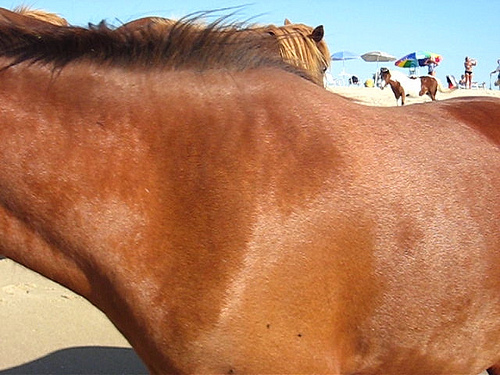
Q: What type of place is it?
A: It is a beach.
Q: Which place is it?
A: It is a beach.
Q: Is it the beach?
A: Yes, it is the beach.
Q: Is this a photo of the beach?
A: Yes, it is showing the beach.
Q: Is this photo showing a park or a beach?
A: It is showing a beach.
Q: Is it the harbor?
A: No, it is the beach.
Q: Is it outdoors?
A: Yes, it is outdoors.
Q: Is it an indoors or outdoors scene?
A: It is outdoors.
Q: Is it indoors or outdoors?
A: It is outdoors.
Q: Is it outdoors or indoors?
A: It is outdoors.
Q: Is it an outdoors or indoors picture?
A: It is outdoors.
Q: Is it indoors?
A: No, it is outdoors.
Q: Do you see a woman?
A: Yes, there is a woman.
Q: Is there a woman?
A: Yes, there is a woman.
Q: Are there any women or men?
A: Yes, there is a woman.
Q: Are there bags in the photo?
A: No, there are no bags.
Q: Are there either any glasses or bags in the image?
A: No, there are no bags or glasses.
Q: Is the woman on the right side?
A: Yes, the woman is on the right of the image.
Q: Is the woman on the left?
A: No, the woman is on the right of the image.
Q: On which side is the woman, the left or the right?
A: The woman is on the right of the image.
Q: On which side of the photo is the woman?
A: The woman is on the right of the image.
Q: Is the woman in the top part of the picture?
A: Yes, the woman is in the top of the image.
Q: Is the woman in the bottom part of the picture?
A: No, the woman is in the top of the image.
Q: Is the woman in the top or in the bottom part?
A: The woman is in the top of the image.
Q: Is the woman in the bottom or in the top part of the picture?
A: The woman is in the top of the image.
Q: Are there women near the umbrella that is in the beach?
A: Yes, there is a woman near the umbrella.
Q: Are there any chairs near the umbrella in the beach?
A: No, there is a woman near the umbrella.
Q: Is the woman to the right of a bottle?
A: No, the woman is to the right of the umbrella.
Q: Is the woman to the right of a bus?
A: No, the woman is to the right of the umbrella.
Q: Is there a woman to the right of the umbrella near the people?
A: Yes, there is a woman to the right of the umbrella.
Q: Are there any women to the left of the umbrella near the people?
A: No, the woman is to the right of the umbrella.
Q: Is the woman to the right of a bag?
A: No, the woman is to the right of the umbrella.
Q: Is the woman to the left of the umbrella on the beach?
A: No, the woman is to the right of the umbrella.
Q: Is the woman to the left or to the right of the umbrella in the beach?
A: The woman is to the right of the umbrella.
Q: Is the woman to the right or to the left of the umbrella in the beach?
A: The woman is to the right of the umbrella.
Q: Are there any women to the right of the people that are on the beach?
A: Yes, there is a woman to the right of the people.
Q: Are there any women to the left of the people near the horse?
A: No, the woman is to the right of the people.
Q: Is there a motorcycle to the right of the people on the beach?
A: No, there is a woman to the right of the people.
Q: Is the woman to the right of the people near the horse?
A: Yes, the woman is to the right of the people.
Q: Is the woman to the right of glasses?
A: No, the woman is to the right of the people.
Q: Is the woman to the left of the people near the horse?
A: No, the woman is to the right of the people.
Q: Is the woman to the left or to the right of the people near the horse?
A: The woman is to the right of the people.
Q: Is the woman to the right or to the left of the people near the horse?
A: The woman is to the right of the people.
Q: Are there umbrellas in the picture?
A: Yes, there is an umbrella.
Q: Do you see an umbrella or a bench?
A: Yes, there is an umbrella.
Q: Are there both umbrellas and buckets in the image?
A: No, there is an umbrella but no buckets.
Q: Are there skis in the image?
A: No, there are no skis.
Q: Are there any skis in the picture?
A: No, there are no skis.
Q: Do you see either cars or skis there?
A: No, there are no skis or cars.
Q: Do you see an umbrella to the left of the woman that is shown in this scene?
A: Yes, there is an umbrella to the left of the woman.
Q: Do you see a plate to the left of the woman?
A: No, there is an umbrella to the left of the woman.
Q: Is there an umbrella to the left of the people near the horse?
A: Yes, there is an umbrella to the left of the people.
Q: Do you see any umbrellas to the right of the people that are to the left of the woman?
A: No, the umbrella is to the left of the people.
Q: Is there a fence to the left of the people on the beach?
A: No, there is an umbrella to the left of the people.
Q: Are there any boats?
A: No, there are no boats.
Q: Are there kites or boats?
A: No, there are no boats or kites.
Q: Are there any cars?
A: No, there are no cars.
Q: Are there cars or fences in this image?
A: No, there are no cars or fences.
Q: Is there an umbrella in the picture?
A: Yes, there is an umbrella.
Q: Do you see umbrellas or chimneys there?
A: Yes, there is an umbrella.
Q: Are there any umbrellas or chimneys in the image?
A: Yes, there is an umbrella.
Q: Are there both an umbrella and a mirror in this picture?
A: No, there is an umbrella but no mirrors.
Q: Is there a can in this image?
A: No, there are no cans.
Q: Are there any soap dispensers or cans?
A: No, there are no cans or soap dispensers.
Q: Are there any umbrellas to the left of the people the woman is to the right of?
A: Yes, there is an umbrella to the left of the people.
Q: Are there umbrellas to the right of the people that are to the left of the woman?
A: No, the umbrella is to the left of the people.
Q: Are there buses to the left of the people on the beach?
A: No, there is an umbrella to the left of the people.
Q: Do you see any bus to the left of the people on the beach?
A: No, there is an umbrella to the left of the people.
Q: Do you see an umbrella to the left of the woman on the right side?
A: Yes, there is an umbrella to the left of the woman.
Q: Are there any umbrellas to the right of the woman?
A: No, the umbrella is to the left of the woman.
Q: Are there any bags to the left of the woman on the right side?
A: No, there is an umbrella to the left of the woman.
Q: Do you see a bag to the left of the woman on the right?
A: No, there is an umbrella to the left of the woman.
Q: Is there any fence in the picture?
A: No, there are no fences.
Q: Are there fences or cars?
A: No, there are no fences or cars.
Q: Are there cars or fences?
A: No, there are no fences or cars.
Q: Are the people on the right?
A: Yes, the people are on the right of the image.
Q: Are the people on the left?
A: No, the people are on the right of the image.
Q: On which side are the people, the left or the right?
A: The people are on the right of the image.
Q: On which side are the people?
A: The people are on the right of the image.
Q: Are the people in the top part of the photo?
A: Yes, the people are in the top of the image.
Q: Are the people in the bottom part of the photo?
A: No, the people are in the top of the image.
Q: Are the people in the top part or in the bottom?
A: The people are in the top of the image.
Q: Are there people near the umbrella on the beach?
A: Yes, there are people near the umbrella.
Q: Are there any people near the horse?
A: Yes, there are people near the horse.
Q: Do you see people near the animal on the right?
A: Yes, there are people near the horse.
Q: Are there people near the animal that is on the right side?
A: Yes, there are people near the horse.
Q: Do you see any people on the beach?
A: Yes, there are people on the beach.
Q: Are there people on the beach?
A: Yes, there are people on the beach.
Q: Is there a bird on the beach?
A: No, there are people on the beach.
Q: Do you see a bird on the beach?
A: No, there are people on the beach.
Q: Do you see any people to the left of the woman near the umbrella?
A: Yes, there are people to the left of the woman.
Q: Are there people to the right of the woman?
A: No, the people are to the left of the woman.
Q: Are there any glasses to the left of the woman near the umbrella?
A: No, there are people to the left of the woman.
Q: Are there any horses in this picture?
A: Yes, there is a horse.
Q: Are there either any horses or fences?
A: Yes, there is a horse.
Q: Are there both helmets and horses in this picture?
A: No, there is a horse but no helmets.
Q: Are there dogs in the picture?
A: No, there are no dogs.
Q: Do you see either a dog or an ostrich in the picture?
A: No, there are no dogs or ostriches.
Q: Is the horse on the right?
A: Yes, the horse is on the right of the image.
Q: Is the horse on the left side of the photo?
A: No, the horse is on the right of the image.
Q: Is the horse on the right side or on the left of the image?
A: The horse is on the right of the image.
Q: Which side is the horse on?
A: The horse is on the right of the image.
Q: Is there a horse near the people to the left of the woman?
A: Yes, there is a horse near the people.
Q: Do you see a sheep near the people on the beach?
A: No, there is a horse near the people.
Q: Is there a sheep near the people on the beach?
A: No, there is a horse near the people.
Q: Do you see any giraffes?
A: No, there are no giraffes.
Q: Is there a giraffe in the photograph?
A: No, there are no giraffes.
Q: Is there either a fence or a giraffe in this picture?
A: No, there are no giraffes or fences.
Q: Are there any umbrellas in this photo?
A: Yes, there is an umbrella.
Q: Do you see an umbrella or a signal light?
A: Yes, there is an umbrella.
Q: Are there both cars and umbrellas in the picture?
A: No, there is an umbrella but no cars.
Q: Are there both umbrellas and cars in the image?
A: No, there is an umbrella but no cars.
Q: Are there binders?
A: No, there are no binders.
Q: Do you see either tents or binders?
A: No, there are no binders or tents.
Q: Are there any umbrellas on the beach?
A: Yes, there is an umbrella on the beach.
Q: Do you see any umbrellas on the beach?
A: Yes, there is an umbrella on the beach.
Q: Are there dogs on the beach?
A: No, there is an umbrella on the beach.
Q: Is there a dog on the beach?
A: No, there is an umbrella on the beach.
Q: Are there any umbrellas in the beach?
A: Yes, there is an umbrella in the beach.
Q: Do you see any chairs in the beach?
A: No, there is an umbrella in the beach.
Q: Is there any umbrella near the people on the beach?
A: Yes, there is an umbrella near the people.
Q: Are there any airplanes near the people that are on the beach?
A: No, there is an umbrella near the people.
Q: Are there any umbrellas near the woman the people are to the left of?
A: Yes, there is an umbrella near the woman.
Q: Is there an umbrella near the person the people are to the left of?
A: Yes, there is an umbrella near the woman.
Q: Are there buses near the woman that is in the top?
A: No, there is an umbrella near the woman.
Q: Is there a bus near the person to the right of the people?
A: No, there is an umbrella near the woman.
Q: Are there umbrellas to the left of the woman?
A: Yes, there is an umbrella to the left of the woman.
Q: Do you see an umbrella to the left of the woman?
A: Yes, there is an umbrella to the left of the woman.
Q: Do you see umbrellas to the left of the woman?
A: Yes, there is an umbrella to the left of the woman.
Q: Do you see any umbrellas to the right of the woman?
A: No, the umbrella is to the left of the woman.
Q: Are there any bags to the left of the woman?
A: No, there is an umbrella to the left of the woman.